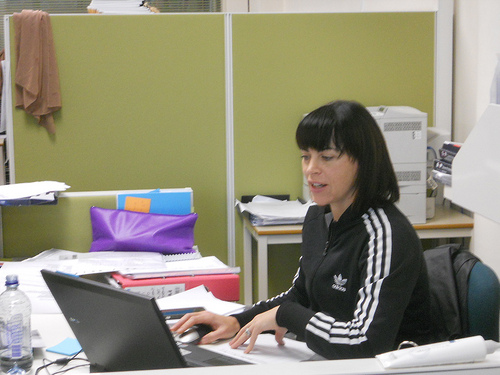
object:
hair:
[295, 97, 401, 214]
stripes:
[306, 205, 392, 342]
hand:
[171, 309, 240, 344]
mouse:
[174, 324, 215, 344]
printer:
[299, 105, 428, 225]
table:
[242, 200, 476, 308]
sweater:
[13, 8, 64, 136]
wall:
[3, 10, 441, 306]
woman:
[168, 98, 434, 360]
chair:
[423, 245, 499, 343]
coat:
[423, 242, 482, 346]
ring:
[245, 327, 251, 336]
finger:
[231, 324, 254, 349]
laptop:
[40, 268, 253, 373]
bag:
[88, 204, 198, 255]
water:
[2, 349, 35, 374]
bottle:
[0, 273, 34, 374]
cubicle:
[0, 11, 498, 375]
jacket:
[229, 195, 433, 361]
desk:
[1, 184, 330, 374]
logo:
[330, 272, 346, 293]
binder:
[106, 268, 241, 301]